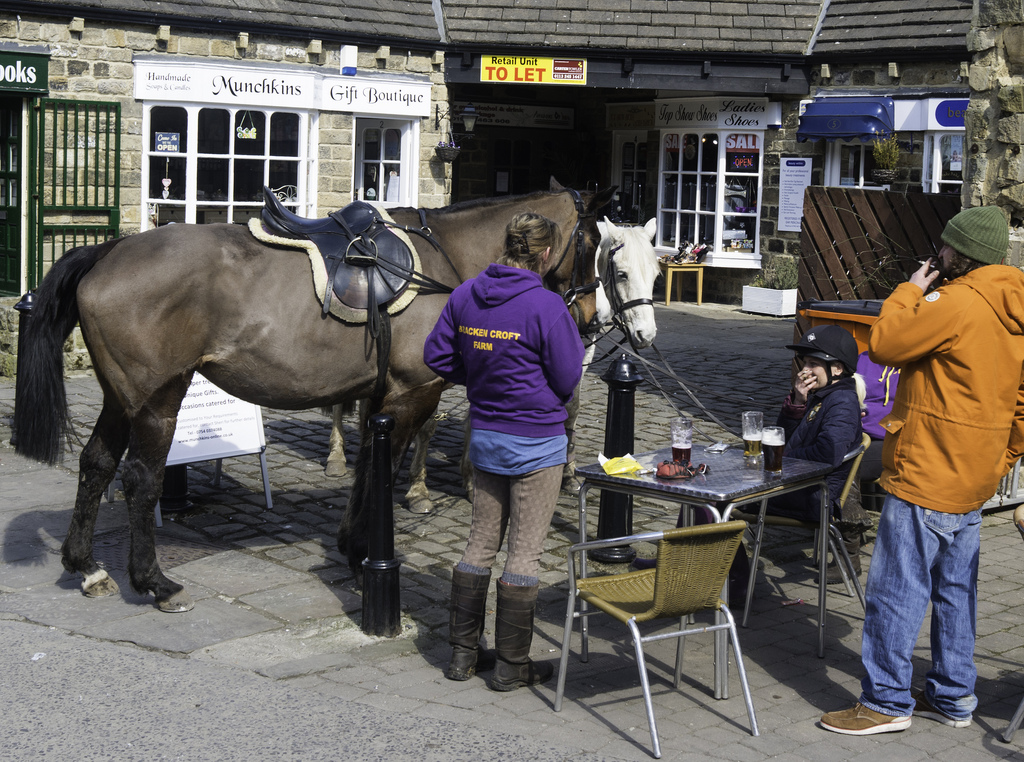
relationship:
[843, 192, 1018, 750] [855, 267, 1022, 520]
man wears jacket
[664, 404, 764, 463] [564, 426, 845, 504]
glasses on table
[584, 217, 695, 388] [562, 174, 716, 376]
head of horse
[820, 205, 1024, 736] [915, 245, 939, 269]
man smoking a cigarette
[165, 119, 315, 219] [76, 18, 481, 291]
window on building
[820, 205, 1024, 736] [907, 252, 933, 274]
man holds cigarrete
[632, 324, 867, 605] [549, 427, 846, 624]
girl behind table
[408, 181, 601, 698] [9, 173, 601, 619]
female in front horse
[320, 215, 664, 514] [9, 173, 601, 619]
horse close horse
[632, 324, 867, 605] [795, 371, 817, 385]
girl covers mouth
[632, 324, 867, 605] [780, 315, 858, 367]
girl wears hat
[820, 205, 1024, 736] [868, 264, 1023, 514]
man wears jacket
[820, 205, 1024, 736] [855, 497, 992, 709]
man wears blue jeans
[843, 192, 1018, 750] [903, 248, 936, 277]
man smokes cigarette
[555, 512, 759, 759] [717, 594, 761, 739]
chair has leg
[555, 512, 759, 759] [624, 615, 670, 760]
chair has leg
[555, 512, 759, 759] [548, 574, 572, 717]
chair has leg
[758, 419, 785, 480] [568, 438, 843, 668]
drink on top of table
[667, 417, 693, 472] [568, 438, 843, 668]
drink on top of table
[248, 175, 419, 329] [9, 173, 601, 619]
saddle on horse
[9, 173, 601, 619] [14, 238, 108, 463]
horse has tail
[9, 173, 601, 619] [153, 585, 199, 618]
horse has hoof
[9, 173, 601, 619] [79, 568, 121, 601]
horse has hoof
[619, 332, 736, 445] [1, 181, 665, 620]
reins in front of horses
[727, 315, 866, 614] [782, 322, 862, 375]
girl wearing helmet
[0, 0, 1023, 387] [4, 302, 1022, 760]
building surrounding square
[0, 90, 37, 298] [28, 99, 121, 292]
door open at doorway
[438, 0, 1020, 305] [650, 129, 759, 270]
shop has window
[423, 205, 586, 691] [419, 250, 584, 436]
female wearing sweatshirt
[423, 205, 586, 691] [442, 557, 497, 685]
female wearing boot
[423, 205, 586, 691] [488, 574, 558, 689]
female wearing boot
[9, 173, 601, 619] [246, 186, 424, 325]
horse wearing saddle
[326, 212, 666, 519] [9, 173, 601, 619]
horse standing in front of horse